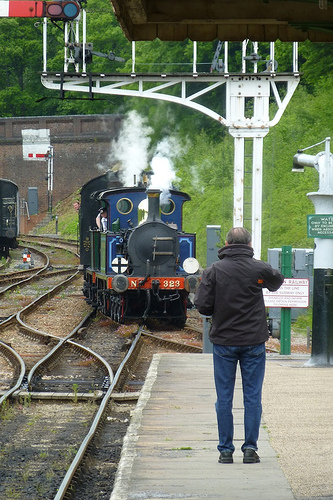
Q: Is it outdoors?
A: Yes, it is outdoors.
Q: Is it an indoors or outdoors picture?
A: It is outdoors.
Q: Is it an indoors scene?
A: No, it is outdoors.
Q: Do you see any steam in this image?
A: Yes, there is steam.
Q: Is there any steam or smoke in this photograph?
A: Yes, there is steam.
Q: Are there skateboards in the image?
A: No, there are no skateboards.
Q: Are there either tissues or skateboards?
A: No, there are no skateboards or tissues.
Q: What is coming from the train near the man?
A: The steam is coming from the train.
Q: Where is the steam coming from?
A: The steam is coming from the train.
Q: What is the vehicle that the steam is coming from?
A: The vehicle is a train.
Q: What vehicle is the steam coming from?
A: The steam is coming from the train.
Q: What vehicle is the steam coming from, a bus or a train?
A: The steam is coming from a train.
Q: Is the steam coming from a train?
A: Yes, the steam is coming from a train.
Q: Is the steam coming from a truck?
A: No, the steam is coming from a train.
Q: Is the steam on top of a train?
A: Yes, the steam is on top of a train.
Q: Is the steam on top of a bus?
A: No, the steam is on top of a train.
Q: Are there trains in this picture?
A: Yes, there is a train.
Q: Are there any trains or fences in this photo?
A: Yes, there is a train.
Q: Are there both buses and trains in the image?
A: No, there is a train but no buses.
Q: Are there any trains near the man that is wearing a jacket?
A: Yes, there is a train near the man.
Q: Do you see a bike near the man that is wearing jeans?
A: No, there is a train near the man.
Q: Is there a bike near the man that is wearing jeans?
A: No, there is a train near the man.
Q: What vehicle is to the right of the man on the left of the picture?
A: The vehicle is a train.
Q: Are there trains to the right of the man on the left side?
A: Yes, there is a train to the right of the man.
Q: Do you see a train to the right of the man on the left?
A: Yes, there is a train to the right of the man.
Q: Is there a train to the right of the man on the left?
A: Yes, there is a train to the right of the man.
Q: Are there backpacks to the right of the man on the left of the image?
A: No, there is a train to the right of the man.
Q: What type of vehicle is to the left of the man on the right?
A: The vehicle is a train.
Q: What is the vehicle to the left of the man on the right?
A: The vehicle is a train.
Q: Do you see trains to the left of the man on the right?
A: Yes, there is a train to the left of the man.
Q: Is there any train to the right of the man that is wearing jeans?
A: No, the train is to the left of the man.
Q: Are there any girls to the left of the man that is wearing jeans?
A: No, there is a train to the left of the man.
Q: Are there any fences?
A: No, there are no fences.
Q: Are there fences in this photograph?
A: No, there are no fences.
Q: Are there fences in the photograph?
A: No, there are no fences.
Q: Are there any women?
A: No, there are no women.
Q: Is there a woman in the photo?
A: No, there are no women.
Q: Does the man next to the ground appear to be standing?
A: Yes, the man is standing.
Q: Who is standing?
A: The man is standing.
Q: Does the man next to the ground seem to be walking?
A: No, the man is standing.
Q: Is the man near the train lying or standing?
A: The man is standing.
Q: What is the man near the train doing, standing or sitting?
A: The man is standing.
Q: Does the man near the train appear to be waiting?
A: Yes, the man is waiting.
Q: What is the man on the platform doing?
A: The man is waiting.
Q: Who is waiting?
A: The man is waiting.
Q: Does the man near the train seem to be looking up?
A: No, the man is waiting.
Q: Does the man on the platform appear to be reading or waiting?
A: The man is waiting.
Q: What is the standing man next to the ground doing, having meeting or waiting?
A: The man is waiting.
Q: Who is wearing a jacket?
A: The man is wearing a jacket.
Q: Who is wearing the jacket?
A: The man is wearing a jacket.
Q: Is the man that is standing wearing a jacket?
A: Yes, the man is wearing a jacket.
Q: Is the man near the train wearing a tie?
A: No, the man is wearing a jacket.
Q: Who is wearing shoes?
A: The man is wearing shoes.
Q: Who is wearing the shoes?
A: The man is wearing shoes.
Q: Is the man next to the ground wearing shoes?
A: Yes, the man is wearing shoes.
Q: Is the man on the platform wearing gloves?
A: No, the man is wearing shoes.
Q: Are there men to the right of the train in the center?
A: Yes, there is a man to the right of the train.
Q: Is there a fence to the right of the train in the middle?
A: No, there is a man to the right of the train.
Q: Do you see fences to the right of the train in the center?
A: No, there is a man to the right of the train.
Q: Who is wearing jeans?
A: The man is wearing jeans.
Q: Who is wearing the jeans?
A: The man is wearing jeans.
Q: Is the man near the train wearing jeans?
A: Yes, the man is wearing jeans.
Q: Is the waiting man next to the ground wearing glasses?
A: No, the man is wearing jeans.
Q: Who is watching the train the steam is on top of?
A: The man is watching the train.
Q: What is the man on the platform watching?
A: The man is watching the train.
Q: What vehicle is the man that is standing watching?
A: The man is watching the train.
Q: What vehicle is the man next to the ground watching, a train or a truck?
A: The man is watching a train.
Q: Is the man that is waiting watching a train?
A: Yes, the man is watching a train.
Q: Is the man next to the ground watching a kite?
A: No, the man is watching a train.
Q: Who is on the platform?
A: The man is on the platform.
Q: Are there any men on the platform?
A: Yes, there is a man on the platform.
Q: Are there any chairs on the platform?
A: No, there is a man on the platform.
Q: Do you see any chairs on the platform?
A: No, there is a man on the platform.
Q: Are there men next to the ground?
A: Yes, there is a man next to the ground.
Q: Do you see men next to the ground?
A: Yes, there is a man next to the ground.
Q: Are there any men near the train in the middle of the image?
A: Yes, there is a man near the train.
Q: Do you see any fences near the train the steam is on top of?
A: No, there is a man near the train.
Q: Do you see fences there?
A: No, there are no fences.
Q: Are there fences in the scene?
A: No, there are no fences.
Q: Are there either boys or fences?
A: No, there are no fences or boys.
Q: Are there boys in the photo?
A: No, there are no boys.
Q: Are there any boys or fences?
A: No, there are no boys or fences.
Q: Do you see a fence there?
A: No, there are no fences.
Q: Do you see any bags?
A: No, there are no bags.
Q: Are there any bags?
A: No, there are no bags.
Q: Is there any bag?
A: No, there are no bags.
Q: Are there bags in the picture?
A: No, there are no bags.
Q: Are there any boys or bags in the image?
A: No, there are no bags or boys.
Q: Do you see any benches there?
A: No, there are no benches.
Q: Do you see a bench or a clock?
A: No, there are no benches or clocks.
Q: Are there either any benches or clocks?
A: No, there are no benches or clocks.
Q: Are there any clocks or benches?
A: No, there are no benches or clocks.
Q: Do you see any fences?
A: No, there are no fences.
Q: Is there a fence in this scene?
A: No, there are no fences.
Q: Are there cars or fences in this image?
A: No, there are no fences or cars.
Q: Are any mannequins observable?
A: No, there are no mannequins.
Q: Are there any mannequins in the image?
A: No, there are no mannequins.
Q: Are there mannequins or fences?
A: No, there are no mannequins or fences.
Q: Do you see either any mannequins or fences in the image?
A: No, there are no mannequins or fences.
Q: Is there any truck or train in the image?
A: Yes, there is a train.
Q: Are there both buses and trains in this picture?
A: No, there is a train but no buses.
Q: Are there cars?
A: No, there are no cars.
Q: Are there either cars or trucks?
A: No, there are no cars or trucks.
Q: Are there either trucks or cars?
A: No, there are no cars or trucks.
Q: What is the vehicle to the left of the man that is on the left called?
A: The vehicle is a train.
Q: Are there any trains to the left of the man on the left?
A: Yes, there is a train to the left of the man.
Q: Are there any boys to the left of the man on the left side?
A: No, there is a train to the left of the man.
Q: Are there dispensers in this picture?
A: No, there are no dispensers.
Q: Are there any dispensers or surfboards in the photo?
A: No, there are no dispensers or surfboards.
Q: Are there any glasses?
A: No, there are no glasses.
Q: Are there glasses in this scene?
A: No, there are no glasses.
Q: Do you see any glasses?
A: No, there are no glasses.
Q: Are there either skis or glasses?
A: No, there are no glasses or skis.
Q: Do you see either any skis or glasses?
A: No, there are no glasses or skis.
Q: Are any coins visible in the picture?
A: No, there are no coins.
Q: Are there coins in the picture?
A: No, there are no coins.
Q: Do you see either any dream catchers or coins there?
A: No, there are no coins or dream catchers.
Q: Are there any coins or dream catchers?
A: No, there are no coins or dream catchers.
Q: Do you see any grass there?
A: Yes, there is grass.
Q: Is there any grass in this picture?
A: Yes, there is grass.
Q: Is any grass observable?
A: Yes, there is grass.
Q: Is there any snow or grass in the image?
A: Yes, there is grass.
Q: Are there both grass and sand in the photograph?
A: No, there is grass but no sand.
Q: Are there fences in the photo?
A: No, there are no fences.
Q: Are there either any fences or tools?
A: No, there are no fences or tools.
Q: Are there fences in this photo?
A: No, there are no fences.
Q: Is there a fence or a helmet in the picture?
A: No, there are no fences or helmets.